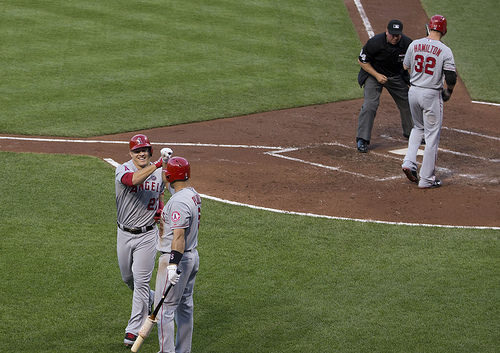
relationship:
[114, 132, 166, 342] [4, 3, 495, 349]
player on field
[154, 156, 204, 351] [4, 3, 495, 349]
player on field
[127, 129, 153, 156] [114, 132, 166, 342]
helmet on player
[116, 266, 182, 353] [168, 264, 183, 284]
baseball bat in hand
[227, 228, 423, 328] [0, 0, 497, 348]
grass on ground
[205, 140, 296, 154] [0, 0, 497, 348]
line on ground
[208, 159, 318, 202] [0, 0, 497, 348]
dirt on ground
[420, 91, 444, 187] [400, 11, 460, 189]
leg of man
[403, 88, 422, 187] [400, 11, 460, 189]
leg of man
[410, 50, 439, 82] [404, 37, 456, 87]
number on jersey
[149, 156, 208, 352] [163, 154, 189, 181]
man wearing helmet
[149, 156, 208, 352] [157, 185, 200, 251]
man wearing jersey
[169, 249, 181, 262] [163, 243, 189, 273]
band around mans wrist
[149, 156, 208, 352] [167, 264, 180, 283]
man wearing glove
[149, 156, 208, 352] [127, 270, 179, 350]
man holding baseball bat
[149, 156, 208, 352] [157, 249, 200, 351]
man wearing pants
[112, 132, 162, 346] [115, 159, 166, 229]
man wearing jersey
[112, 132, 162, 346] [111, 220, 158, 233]
man wearing belt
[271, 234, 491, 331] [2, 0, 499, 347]
grass on baseball field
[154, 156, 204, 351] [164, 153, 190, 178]
player wearing a helmet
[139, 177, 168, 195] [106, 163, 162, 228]
logo on jersey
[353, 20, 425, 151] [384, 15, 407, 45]
umpire wears hat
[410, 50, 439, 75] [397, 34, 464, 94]
number on jersey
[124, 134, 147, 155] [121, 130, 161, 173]
helmet on head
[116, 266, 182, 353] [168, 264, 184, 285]
baseball bat on hand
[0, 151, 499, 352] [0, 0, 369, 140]
grass on infield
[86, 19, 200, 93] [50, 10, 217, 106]
grass on infield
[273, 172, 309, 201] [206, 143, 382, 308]
dirt on field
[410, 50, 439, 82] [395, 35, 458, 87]
number on jersey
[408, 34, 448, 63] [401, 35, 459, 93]
name on jersey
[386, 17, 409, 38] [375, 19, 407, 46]
cap on head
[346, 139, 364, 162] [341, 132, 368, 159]
foot in shoe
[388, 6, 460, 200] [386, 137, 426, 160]
player next plate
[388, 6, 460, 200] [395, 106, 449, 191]
player has legs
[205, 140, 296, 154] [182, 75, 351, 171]
line on ground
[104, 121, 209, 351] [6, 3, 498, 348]
players in photo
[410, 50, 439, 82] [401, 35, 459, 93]
number on jersey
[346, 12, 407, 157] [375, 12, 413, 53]
man has head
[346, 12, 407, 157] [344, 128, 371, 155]
man has foot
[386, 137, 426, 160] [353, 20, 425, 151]
plate under umpire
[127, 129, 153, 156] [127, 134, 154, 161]
helmet on head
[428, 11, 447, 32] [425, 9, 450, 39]
helmet on head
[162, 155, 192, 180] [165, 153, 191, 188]
helmet on head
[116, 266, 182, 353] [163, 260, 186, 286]
baseball bat in hand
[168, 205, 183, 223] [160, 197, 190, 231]
patch on sleeve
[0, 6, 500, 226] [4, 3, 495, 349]
dirt on field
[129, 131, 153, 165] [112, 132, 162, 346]
head on man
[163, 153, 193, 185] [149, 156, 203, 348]
head on man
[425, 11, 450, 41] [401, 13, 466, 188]
head on man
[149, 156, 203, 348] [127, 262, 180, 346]
man holding bat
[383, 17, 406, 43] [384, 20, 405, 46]
hat on head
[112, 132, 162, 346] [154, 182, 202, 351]
man wearing uniform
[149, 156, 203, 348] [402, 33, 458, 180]
man wearing uniform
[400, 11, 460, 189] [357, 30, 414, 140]
man wearing uniform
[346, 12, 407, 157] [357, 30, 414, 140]
man wearing uniform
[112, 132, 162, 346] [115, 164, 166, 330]
man wearing uniform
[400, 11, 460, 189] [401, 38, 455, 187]
man wearing uniform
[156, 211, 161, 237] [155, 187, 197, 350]
dirt on uniform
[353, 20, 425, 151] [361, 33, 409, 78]
umpire wearing shirt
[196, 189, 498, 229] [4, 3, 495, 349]
line on field